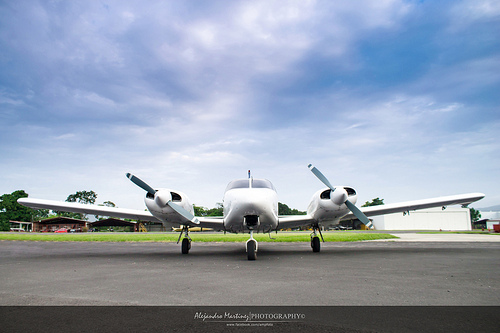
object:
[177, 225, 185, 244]
hatch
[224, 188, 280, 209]
nose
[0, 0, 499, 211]
sky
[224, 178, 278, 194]
windows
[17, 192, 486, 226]
wings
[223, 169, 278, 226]
cockpit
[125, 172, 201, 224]
propeller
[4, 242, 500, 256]
shadow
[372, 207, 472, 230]
building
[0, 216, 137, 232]
buildings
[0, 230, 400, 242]
grass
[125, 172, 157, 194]
blade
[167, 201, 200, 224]
blade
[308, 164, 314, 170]
stripe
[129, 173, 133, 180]
stripe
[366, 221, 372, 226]
stripe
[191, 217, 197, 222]
stripe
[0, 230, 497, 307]
ground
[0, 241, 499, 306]
asphalt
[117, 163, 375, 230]
propellors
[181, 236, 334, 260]
tires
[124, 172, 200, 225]
engine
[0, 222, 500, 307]
airport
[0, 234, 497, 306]
cement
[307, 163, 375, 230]
blades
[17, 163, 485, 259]
airplane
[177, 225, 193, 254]
landing gear